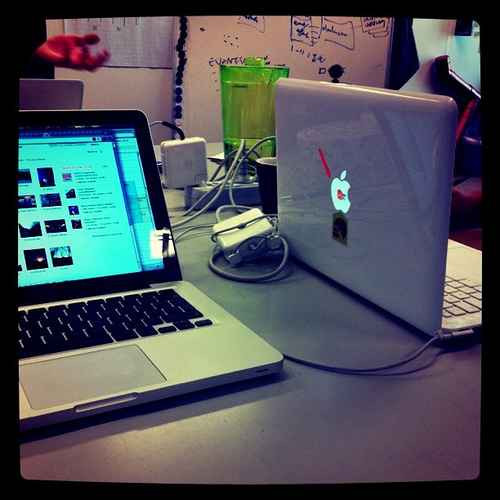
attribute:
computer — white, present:
[258, 63, 477, 359]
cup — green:
[212, 60, 277, 184]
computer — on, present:
[23, 95, 286, 447]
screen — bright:
[25, 135, 169, 275]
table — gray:
[32, 262, 478, 476]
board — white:
[172, 16, 395, 85]